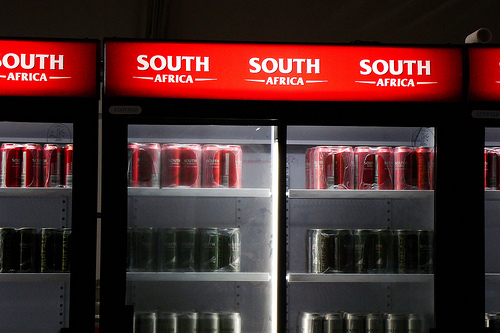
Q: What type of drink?
A: Sodas.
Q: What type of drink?
A: Soda.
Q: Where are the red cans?
A: On the top shelf.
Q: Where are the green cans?
A: On the middle shelf.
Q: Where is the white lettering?
A: On the red sign.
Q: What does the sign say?
A: South Africa.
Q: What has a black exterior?
A: The fridge.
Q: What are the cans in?
A: The fridge.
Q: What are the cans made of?
A: Aluminum.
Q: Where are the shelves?
A: Inside the fridge.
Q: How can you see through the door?
A: Made of glass.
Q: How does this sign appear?
A: Well lit.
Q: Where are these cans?
A: On shelf.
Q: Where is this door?
A: On display case.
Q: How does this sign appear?
A: Red.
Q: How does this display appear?
A: Lit.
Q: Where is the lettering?
A: On sign.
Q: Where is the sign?
A: On cooler.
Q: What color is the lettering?
A: White.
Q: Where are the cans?
A: On rows.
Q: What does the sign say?
A: South Africa.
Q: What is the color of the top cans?
A: Red.